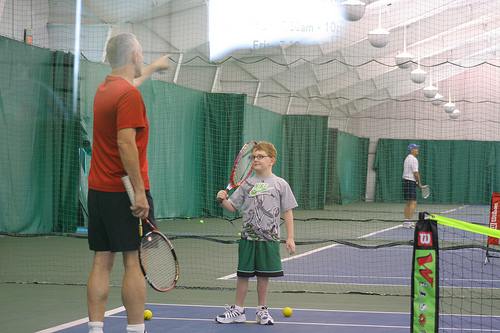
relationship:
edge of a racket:
[156, 251, 186, 333] [118, 168, 187, 294]